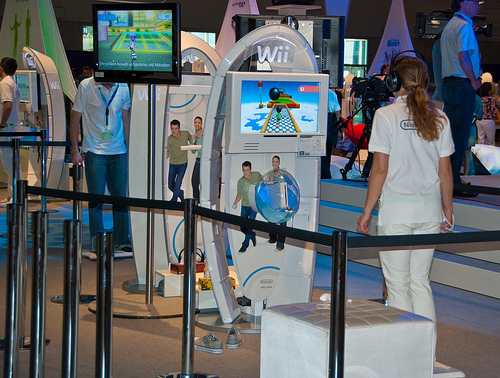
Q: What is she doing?
A: Playing.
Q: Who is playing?
A: The girl.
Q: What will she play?
A: Games.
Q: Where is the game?
A: In front of her.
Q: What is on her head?
A: Headphones.